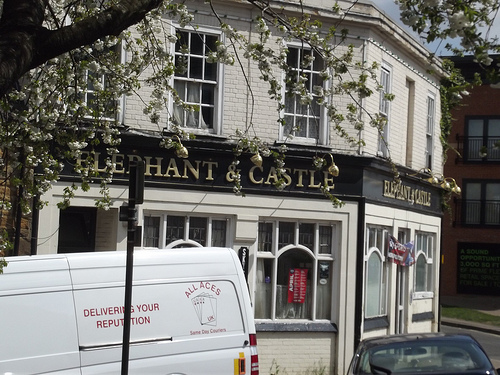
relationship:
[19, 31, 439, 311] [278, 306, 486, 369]
building on corner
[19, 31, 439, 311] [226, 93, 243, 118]
building has brick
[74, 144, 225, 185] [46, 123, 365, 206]
elephant on sign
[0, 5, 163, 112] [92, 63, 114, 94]
tree has blossoms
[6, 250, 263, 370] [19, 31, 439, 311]
van by building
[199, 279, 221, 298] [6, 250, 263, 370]
aces on van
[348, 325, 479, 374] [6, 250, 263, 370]
car behind van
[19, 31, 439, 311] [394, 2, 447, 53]
building in daytime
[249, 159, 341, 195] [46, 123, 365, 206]
castle on sign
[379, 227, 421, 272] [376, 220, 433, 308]
flag in window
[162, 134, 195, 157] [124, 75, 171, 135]
flowers on branches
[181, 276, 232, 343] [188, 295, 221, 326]
logo with cards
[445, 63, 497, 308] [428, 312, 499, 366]
building by street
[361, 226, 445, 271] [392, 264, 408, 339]
banner over doorway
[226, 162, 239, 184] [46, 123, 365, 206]
ampersand on sign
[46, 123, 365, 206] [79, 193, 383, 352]
sign on shop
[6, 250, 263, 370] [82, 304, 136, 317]
van for delivery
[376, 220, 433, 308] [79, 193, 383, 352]
window of shop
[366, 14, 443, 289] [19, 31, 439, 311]
front of building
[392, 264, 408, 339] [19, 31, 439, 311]
doorway into building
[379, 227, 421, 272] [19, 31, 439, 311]
flag on building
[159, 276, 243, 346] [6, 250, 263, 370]
design on van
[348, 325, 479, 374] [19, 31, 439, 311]
car by building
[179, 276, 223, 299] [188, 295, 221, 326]
letters above cards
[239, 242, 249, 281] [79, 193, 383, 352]
name on store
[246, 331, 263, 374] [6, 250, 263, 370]
light on vehicle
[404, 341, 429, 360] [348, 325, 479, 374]
mirror on car